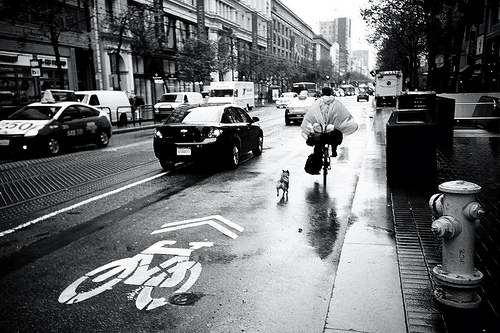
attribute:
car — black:
[153, 102, 264, 172]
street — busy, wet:
[0, 94, 375, 329]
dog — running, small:
[274, 167, 291, 201]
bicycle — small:
[318, 134, 332, 184]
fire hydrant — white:
[426, 179, 487, 310]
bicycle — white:
[56, 238, 216, 313]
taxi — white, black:
[1, 88, 113, 158]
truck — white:
[207, 80, 255, 113]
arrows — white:
[150, 212, 244, 242]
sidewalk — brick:
[391, 124, 499, 332]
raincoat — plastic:
[300, 95, 359, 139]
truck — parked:
[371, 69, 403, 108]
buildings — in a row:
[0, 0, 371, 113]